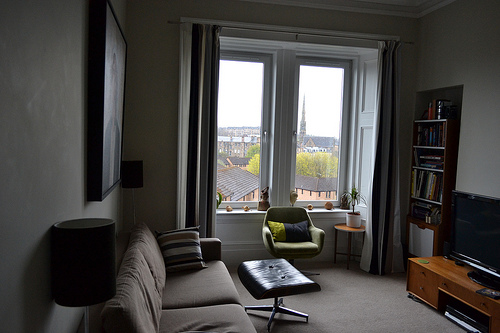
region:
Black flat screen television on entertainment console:
[438, 188, 498, 288]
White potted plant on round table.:
[342, 185, 367, 229]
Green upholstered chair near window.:
[262, 199, 324, 281]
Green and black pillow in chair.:
[266, 217, 312, 242]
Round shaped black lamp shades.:
[51, 153, 148, 305]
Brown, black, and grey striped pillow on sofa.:
[155, 225, 205, 273]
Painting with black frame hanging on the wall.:
[87, 0, 124, 200]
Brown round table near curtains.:
[330, 220, 360, 270]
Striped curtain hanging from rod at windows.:
[181, 16, 408, 276]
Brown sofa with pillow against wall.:
[97, 220, 249, 331]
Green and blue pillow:
[268, 220, 309, 240]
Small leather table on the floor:
[241, 253, 319, 331]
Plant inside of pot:
[340, 188, 366, 229]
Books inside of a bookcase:
[407, 120, 448, 222]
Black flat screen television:
[440, 187, 499, 277]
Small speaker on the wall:
[117, 155, 146, 191]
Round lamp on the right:
[40, 211, 125, 329]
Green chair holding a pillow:
[255, 202, 327, 259]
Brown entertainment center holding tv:
[407, 190, 499, 329]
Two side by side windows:
[215, 44, 352, 211]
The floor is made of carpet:
[324, 272, 396, 328]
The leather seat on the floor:
[235, 245, 320, 331]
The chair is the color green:
[260, 203, 329, 278]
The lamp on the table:
[47, 210, 119, 329]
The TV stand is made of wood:
[401, 253, 498, 331]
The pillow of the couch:
[156, 223, 209, 275]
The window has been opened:
[174, 18, 399, 266]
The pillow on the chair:
[262, 213, 312, 246]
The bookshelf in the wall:
[401, 94, 466, 271]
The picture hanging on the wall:
[78, 3, 132, 206]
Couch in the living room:
[103, 220, 253, 332]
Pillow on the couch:
[155, 224, 210, 276]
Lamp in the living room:
[48, 217, 119, 332]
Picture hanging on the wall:
[88, 0, 127, 204]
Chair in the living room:
[261, 204, 325, 263]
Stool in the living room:
[333, 223, 366, 270]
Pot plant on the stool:
[339, 185, 366, 227]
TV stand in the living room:
[406, 254, 498, 331]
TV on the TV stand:
[444, 189, 498, 299]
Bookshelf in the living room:
[403, 82, 463, 262]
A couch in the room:
[135, 255, 210, 329]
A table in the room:
[242, 250, 326, 321]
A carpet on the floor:
[325, 272, 390, 321]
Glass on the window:
[245, 57, 332, 182]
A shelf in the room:
[405, 118, 453, 214]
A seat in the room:
[260, 203, 322, 265]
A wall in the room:
[33, 41, 68, 111]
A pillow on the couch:
[162, 230, 209, 291]